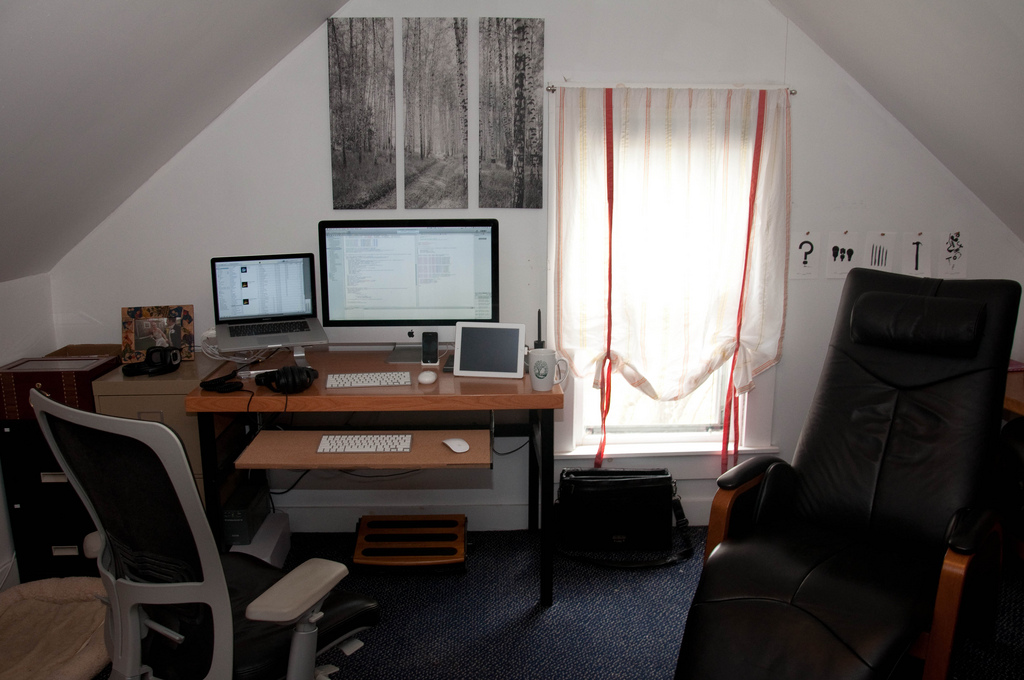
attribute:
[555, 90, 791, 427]
curtain — white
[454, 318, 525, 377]
tablet — white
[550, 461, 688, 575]
laptop bag — black, carrying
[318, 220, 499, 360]
computer — on, black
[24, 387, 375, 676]
office chair — grey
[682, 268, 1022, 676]
chair — wood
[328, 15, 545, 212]
sepia triptych — forest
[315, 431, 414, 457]
computer keyboard — white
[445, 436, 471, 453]
computer mouse — white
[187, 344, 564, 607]
computer desk — wood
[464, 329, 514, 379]
screen — black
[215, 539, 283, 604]
cushion — black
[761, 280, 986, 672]
cushions — blacks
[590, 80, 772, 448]
drawstring — red